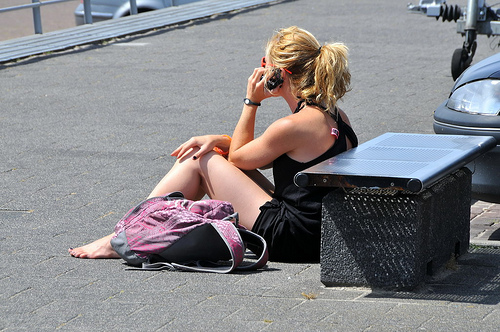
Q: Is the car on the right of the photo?
A: Yes, the car is on the right of the image.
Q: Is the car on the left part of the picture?
A: No, the car is on the right of the image.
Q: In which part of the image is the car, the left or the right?
A: The car is on the right of the image.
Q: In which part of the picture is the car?
A: The car is on the right of the image.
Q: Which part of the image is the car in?
A: The car is on the right of the image.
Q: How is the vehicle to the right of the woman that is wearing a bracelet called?
A: The vehicle is a car.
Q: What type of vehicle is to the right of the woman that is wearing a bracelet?
A: The vehicle is a car.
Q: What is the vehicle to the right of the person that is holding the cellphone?
A: The vehicle is a car.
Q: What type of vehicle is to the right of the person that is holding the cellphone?
A: The vehicle is a car.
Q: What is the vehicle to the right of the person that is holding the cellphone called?
A: The vehicle is a car.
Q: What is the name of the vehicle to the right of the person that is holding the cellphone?
A: The vehicle is a car.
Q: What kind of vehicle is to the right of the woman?
A: The vehicle is a car.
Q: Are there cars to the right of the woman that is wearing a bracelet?
A: Yes, there is a car to the right of the woman.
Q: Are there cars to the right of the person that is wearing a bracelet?
A: Yes, there is a car to the right of the woman.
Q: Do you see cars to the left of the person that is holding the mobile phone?
A: No, the car is to the right of the woman.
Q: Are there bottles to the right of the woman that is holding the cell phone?
A: No, there is a car to the right of the woman.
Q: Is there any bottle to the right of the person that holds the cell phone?
A: No, there is a car to the right of the woman.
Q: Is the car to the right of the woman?
A: Yes, the car is to the right of the woman.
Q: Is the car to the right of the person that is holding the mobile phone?
A: Yes, the car is to the right of the woman.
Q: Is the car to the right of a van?
A: No, the car is to the right of the woman.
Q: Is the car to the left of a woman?
A: No, the car is to the right of a woman.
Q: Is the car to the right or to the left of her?
A: The car is to the right of the woman.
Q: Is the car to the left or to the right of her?
A: The car is to the right of the woman.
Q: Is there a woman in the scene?
A: Yes, there is a woman.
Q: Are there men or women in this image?
A: Yes, there is a woman.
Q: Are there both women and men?
A: No, there is a woman but no men.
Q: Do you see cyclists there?
A: No, there are no cyclists.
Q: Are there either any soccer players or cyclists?
A: No, there are no cyclists or soccer players.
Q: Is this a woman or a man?
A: This is a woman.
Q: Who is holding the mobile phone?
A: The woman is holding the mobile phone.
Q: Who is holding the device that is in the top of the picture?
A: The woman is holding the mobile phone.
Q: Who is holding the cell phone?
A: The woman is holding the mobile phone.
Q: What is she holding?
A: The woman is holding the cell phone.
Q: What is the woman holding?
A: The woman is holding the cell phone.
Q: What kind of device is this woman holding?
A: The woman is holding the mobile phone.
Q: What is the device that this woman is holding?
A: The device is a cell phone.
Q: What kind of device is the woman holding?
A: The woman is holding the mobile phone.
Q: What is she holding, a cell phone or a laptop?
A: The woman is holding a cell phone.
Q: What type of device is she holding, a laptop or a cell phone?
A: The woman is holding a cell phone.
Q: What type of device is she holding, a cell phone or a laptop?
A: The woman is holding a cell phone.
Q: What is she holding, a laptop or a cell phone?
A: The woman is holding a cell phone.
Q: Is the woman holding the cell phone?
A: Yes, the woman is holding the cell phone.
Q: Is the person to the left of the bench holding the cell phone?
A: Yes, the woman is holding the cell phone.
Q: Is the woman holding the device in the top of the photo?
A: Yes, the woman is holding the cell phone.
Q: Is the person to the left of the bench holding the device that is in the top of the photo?
A: Yes, the woman is holding the cell phone.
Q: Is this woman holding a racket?
A: No, the woman is holding the cell phone.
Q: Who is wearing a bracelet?
A: The woman is wearing a bracelet.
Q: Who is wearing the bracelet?
A: The woman is wearing a bracelet.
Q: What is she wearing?
A: The woman is wearing a bracelet.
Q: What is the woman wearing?
A: The woman is wearing a bracelet.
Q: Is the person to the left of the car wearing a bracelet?
A: Yes, the woman is wearing a bracelet.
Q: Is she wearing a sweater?
A: No, the woman is wearing a bracelet.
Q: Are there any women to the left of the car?
A: Yes, there is a woman to the left of the car.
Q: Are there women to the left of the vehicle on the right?
A: Yes, there is a woman to the left of the car.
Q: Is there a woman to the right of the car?
A: No, the woman is to the left of the car.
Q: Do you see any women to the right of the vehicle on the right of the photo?
A: No, the woman is to the left of the car.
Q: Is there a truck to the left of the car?
A: No, there is a woman to the left of the car.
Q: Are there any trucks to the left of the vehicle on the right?
A: No, there is a woman to the left of the car.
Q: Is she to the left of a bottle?
A: No, the woman is to the left of the car.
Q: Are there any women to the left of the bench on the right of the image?
A: Yes, there is a woman to the left of the bench.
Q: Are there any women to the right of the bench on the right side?
A: No, the woman is to the left of the bench.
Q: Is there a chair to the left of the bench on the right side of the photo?
A: No, there is a woman to the left of the bench.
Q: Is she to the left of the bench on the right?
A: Yes, the woman is to the left of the bench.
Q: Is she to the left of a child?
A: No, the woman is to the left of the bench.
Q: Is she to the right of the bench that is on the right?
A: No, the woman is to the left of the bench.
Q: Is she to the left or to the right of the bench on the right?
A: The woman is to the left of the bench.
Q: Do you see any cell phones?
A: Yes, there is a cell phone.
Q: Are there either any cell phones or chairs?
A: Yes, there is a cell phone.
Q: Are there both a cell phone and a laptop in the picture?
A: No, there is a cell phone but no laptops.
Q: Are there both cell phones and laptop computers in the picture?
A: No, there is a cell phone but no laptops.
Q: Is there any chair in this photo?
A: No, there are no chairs.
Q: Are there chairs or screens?
A: No, there are no chairs or screens.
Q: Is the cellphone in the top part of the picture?
A: Yes, the cellphone is in the top of the image.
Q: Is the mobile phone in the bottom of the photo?
A: No, the mobile phone is in the top of the image.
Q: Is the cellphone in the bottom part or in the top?
A: The cellphone is in the top of the image.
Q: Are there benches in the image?
A: Yes, there is a bench.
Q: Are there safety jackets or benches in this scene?
A: Yes, there is a bench.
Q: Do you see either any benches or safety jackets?
A: Yes, there is a bench.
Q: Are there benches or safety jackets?
A: Yes, there is a bench.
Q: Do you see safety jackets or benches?
A: Yes, there is a bench.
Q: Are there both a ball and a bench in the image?
A: No, there is a bench but no balls.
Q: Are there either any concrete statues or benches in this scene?
A: Yes, there is a concrete bench.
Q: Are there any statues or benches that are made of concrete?
A: Yes, the bench is made of concrete.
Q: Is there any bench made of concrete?
A: Yes, there is a bench that is made of concrete.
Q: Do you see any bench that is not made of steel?
A: Yes, there is a bench that is made of concrete.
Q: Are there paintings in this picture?
A: No, there are no paintings.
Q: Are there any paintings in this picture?
A: No, there are no paintings.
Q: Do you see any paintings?
A: No, there are no paintings.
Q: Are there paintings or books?
A: No, there are no paintings or books.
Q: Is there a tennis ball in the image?
A: No, there are no tennis balls.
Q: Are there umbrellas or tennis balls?
A: No, there are no tennis balls or umbrellas.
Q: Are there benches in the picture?
A: Yes, there is a bench.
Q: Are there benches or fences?
A: Yes, there is a bench.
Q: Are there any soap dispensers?
A: No, there are no soap dispensers.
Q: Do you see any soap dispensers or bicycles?
A: No, there are no soap dispensers or bicycles.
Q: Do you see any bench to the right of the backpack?
A: Yes, there is a bench to the right of the backpack.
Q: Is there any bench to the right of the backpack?
A: Yes, there is a bench to the right of the backpack.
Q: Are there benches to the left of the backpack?
A: No, the bench is to the right of the backpack.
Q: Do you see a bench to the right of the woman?
A: Yes, there is a bench to the right of the woman.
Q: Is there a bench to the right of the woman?
A: Yes, there is a bench to the right of the woman.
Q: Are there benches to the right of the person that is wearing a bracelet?
A: Yes, there is a bench to the right of the woman.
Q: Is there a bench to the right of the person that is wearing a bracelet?
A: Yes, there is a bench to the right of the woman.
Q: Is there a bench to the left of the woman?
A: No, the bench is to the right of the woman.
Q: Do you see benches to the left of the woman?
A: No, the bench is to the right of the woman.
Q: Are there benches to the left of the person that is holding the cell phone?
A: No, the bench is to the right of the woman.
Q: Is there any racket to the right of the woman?
A: No, there is a bench to the right of the woman.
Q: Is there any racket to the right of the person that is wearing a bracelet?
A: No, there is a bench to the right of the woman.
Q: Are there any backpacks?
A: Yes, there is a backpack.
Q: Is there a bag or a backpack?
A: Yes, there is a backpack.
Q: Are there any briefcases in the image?
A: No, there are no briefcases.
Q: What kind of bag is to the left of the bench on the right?
A: The bag is a backpack.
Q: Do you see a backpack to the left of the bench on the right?
A: Yes, there is a backpack to the left of the bench.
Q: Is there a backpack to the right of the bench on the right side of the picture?
A: No, the backpack is to the left of the bench.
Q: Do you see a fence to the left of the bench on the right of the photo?
A: No, there is a backpack to the left of the bench.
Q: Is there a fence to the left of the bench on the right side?
A: No, there is a backpack to the left of the bench.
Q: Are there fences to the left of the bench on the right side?
A: No, there is a backpack to the left of the bench.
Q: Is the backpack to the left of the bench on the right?
A: Yes, the backpack is to the left of the bench.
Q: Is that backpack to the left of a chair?
A: No, the backpack is to the left of the bench.